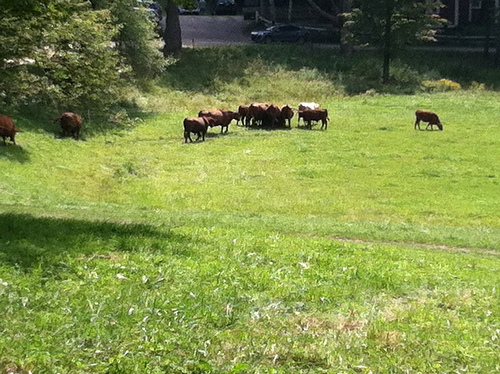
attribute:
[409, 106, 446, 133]
cow — brown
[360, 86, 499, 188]
grass — green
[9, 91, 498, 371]
short grass — green, yellow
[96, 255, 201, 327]
grass — short, green, yellow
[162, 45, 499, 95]
weeds — yellow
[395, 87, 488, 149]
cow — brown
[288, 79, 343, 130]
cow — brown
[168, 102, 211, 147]
cow — brown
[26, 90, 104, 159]
cow — brown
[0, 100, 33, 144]
cow — brown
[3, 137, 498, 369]
grass — short, yellow, green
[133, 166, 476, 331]
grass — yellow-green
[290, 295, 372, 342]
grass — yellow, green, short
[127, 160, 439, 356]
grass — short, yellow, green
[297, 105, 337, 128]
cow — brown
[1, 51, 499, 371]
field — green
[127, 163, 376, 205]
grass — green, yellow, short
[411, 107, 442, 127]
cow — brown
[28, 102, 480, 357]
field — green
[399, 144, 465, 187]
grass — green, short, yellow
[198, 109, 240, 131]
cow — brown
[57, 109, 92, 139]
cow — brown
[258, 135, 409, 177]
grass — green, yellow, short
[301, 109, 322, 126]
cow — brown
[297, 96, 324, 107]
cow — white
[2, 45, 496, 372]
grass — yellow, short, green, yellow-green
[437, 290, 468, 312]
grass — short, yellow and green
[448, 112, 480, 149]
grass — short, yellow and green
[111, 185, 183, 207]
grass — short, yellow and green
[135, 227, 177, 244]
grass — short, yellow and green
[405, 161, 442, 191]
grass — short, yellow and green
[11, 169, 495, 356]
grass — green, yellow , short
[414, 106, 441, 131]
cow — brown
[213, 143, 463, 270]
field — green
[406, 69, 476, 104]
flowers — yellow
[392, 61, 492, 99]
weeds — yellow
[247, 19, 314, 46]
sedan — silver, blue, four door sedan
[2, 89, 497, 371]
grass — short, yellow, green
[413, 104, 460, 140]
cow — brown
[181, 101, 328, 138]
cows — brown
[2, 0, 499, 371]
field — grassy, green